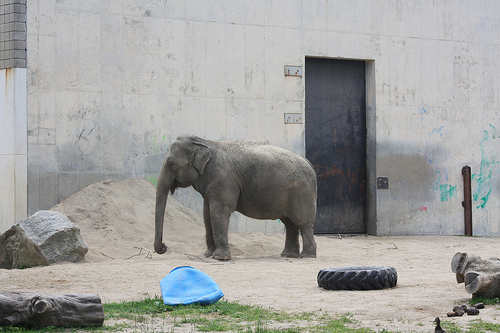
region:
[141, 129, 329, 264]
a large grey elephant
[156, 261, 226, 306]
blue colored item on the ground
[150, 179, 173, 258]
long trunk of an elephant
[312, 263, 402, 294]
large rubber used tire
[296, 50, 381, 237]
tall metal black door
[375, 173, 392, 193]
control panel near door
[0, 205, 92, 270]
large stone in the sand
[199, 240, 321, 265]
elephant's feet in the sand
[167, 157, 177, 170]
one eye of the elephant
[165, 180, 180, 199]
elephant's open mouth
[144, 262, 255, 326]
a flat blue ball on the ground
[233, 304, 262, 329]
grass patches growing in the dirt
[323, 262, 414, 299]
an old rubber tire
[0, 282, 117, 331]
a gray log on the ground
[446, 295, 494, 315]
elephant dung in the dirt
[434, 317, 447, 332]
a black ducking watching the elephant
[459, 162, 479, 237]
a metal post against the wall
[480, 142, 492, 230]
green graffiti on the wall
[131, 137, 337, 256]
a dusty gray elephant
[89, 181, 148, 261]
a pile of sand against the wall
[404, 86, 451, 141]
part of a wall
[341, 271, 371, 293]
edge of a tyre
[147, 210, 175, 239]
trunk of an elephant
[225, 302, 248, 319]
part of some grass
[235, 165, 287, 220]
stomach of an elephant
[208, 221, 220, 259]
part of a leg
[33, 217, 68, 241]
part of a rock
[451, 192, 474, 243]
part of a post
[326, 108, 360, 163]
part of a door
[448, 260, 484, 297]
part of a log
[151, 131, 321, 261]
an elephant standing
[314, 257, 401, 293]
one black tire on ground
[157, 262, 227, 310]
a squished blue ball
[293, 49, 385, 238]
a tall black door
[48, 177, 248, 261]
a sand pile against wall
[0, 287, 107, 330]
a tree log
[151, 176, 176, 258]
the elephants trunk is straight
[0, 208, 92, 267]
a large grey rock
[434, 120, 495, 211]
green paint on the wall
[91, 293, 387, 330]
a small grassy area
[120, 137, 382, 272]
gray elephant facing to the left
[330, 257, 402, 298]
Black tire next to elephant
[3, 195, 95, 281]
gray rock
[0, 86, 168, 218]
Gray wall next to elephant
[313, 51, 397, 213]
Black door behind elephant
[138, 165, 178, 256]
Long trunk on the elephant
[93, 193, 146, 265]
gray dirt near elephant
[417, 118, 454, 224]
Blue stuff on the wall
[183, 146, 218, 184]
Big ears on elephant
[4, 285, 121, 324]
Log on the grass